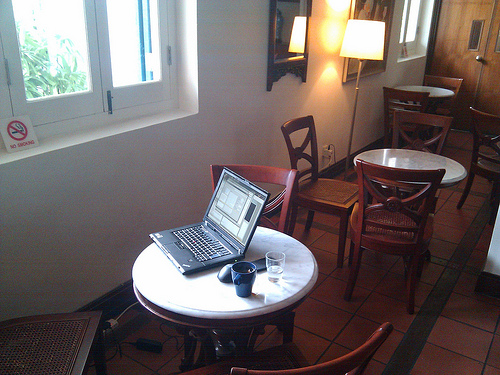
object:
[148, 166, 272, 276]
laptop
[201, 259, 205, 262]
buttons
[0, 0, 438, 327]
wall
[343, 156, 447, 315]
chair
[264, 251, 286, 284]
glass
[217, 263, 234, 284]
mouse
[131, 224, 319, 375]
table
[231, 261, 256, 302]
cup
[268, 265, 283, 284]
water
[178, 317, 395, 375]
chair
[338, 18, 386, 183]
lamp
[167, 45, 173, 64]
hinge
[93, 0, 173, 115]
window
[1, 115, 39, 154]
no smoking sign